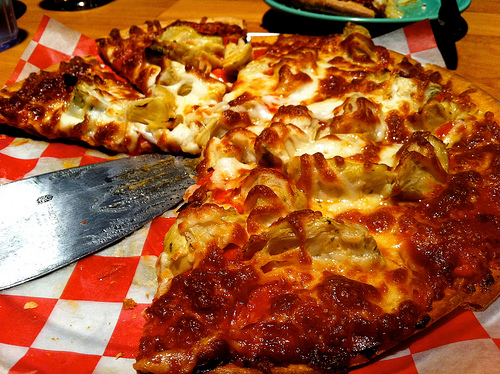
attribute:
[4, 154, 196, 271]
utensil — silver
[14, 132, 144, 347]
paper — checked, red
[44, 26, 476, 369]
pizza — cut, crispy, sliced, red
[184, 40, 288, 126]
cheese — melted, white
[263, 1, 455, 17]
plate — green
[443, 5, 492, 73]
table — wood, wooden, brown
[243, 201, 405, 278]
peppers — green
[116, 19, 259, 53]
crust — brown